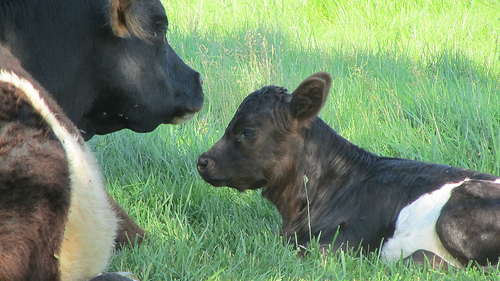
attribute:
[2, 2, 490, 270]
cows — sitting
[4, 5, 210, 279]
cow — adult, black, white, big, mother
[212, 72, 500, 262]
cow — brown, baby, resting, small, young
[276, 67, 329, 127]
ears — perked, small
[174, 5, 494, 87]
grass — green, tall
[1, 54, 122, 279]
torso — brown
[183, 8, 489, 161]
field — grassy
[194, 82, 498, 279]
calf — brown, lying down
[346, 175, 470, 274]
spots — white